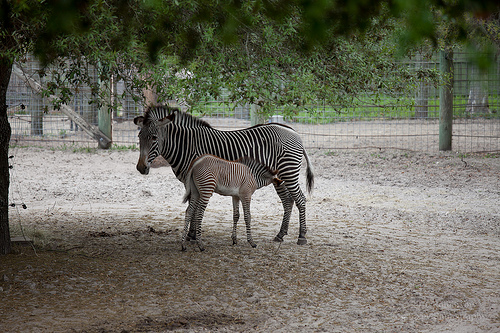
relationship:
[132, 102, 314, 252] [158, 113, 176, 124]
zebra has ear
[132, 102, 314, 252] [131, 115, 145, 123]
zebra has ear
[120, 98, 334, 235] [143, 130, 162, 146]
zebra has eye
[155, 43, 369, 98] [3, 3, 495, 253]
green leaves on tree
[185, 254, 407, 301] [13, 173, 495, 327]
foot prints on sand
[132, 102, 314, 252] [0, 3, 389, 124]
zebra under tree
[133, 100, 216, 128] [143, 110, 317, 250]
hair on zebra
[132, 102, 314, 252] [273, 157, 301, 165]
zebra covered in stripe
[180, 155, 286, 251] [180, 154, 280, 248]
calf covered in stripes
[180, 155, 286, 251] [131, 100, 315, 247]
calf nursing from mother